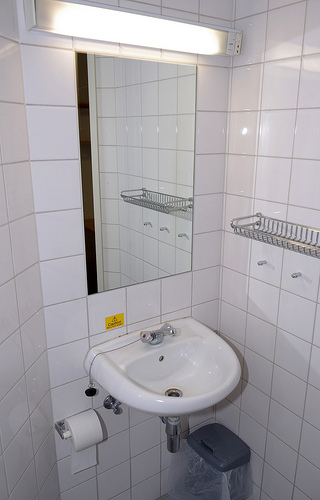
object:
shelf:
[230, 212, 319, 258]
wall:
[0, 1, 320, 497]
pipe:
[165, 423, 182, 454]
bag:
[166, 443, 253, 499]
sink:
[123, 333, 232, 401]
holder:
[22, 0, 244, 60]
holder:
[55, 409, 103, 443]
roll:
[64, 408, 104, 453]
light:
[19, 3, 247, 62]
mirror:
[74, 48, 196, 297]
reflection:
[119, 187, 192, 215]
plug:
[84, 386, 99, 399]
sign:
[105, 312, 124, 331]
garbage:
[186, 420, 251, 499]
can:
[185, 421, 252, 500]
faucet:
[140, 322, 177, 346]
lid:
[185, 420, 252, 473]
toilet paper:
[64, 408, 104, 476]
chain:
[87, 334, 154, 384]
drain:
[165, 386, 183, 400]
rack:
[229, 212, 319, 261]